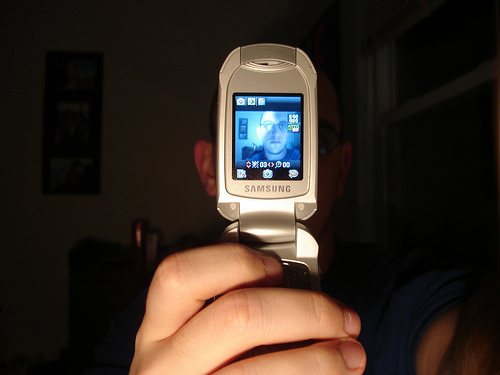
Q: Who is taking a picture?
A: A man.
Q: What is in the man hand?
A: Phone.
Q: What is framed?
A: Picture.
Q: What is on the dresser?
A: Stuff.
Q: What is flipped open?
A: Phone.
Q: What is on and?
A: Camera.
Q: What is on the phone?
A: Fingers.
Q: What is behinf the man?
A: Window.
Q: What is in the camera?
A: Human face.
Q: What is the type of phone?
A: Flip phone.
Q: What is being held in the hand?
A: Phone.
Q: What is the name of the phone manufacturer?
A: Samsung.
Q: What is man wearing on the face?
A: Glasses.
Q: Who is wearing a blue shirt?
A: Person on screen.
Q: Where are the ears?
A: On phone owner.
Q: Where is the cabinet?
A: Behind man.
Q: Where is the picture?
A: On wall.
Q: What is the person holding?
A: Cellphone.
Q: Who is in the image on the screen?
A: The person holding the cellphone.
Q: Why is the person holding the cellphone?
A: Taking a selfie.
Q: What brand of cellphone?
A: Samsung.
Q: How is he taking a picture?
A: Camera phone.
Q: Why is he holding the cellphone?
A: To take a picture.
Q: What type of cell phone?
A: Flip phone.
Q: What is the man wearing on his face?
A: Glasses.